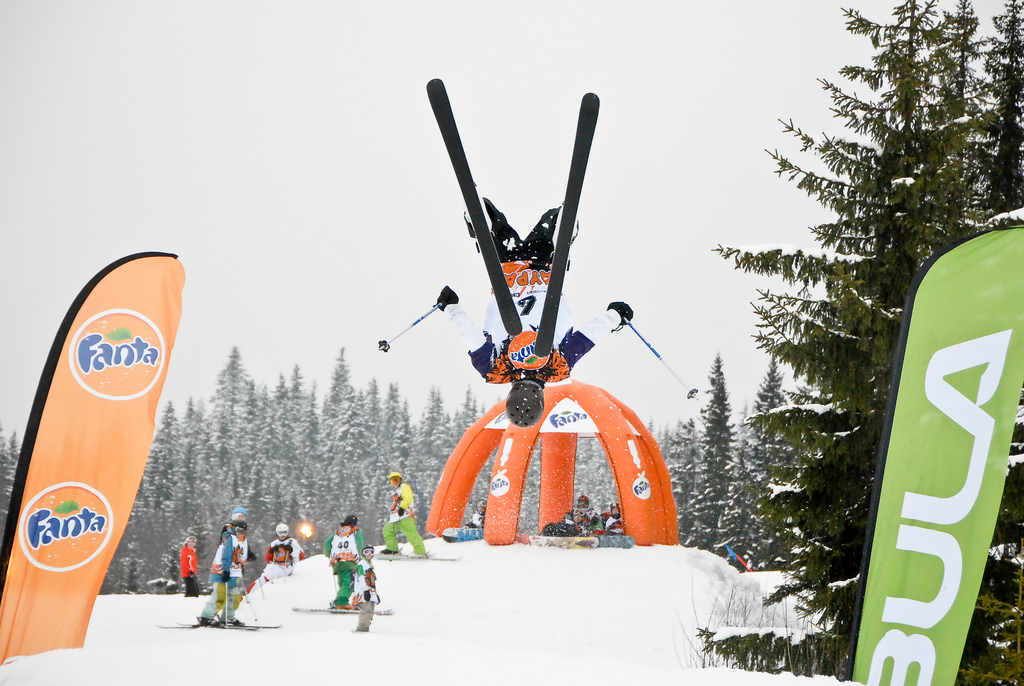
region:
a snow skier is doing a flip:
[366, 72, 708, 439]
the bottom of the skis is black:
[426, 73, 605, 358]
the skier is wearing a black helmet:
[502, 376, 548, 431]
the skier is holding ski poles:
[373, 284, 705, 417]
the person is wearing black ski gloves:
[432, 285, 641, 328]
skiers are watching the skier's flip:
[173, 465, 453, 628]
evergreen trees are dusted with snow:
[3, 323, 804, 609]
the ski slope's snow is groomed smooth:
[12, 534, 832, 683]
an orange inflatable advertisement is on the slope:
[420, 379, 680, 548]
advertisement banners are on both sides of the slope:
[10, 244, 1016, 666]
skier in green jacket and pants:
[318, 508, 367, 613]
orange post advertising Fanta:
[4, 250, 188, 659]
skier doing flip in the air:
[374, 75, 704, 429]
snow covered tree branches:
[174, 348, 432, 491]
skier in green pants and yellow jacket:
[381, 471, 430, 561]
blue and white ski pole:
[623, 310, 706, 406]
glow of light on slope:
[294, 519, 315, 536]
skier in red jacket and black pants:
[175, 531, 202, 598]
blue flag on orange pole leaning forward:
[724, 541, 751, 571]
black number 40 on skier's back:
[334, 537, 351, 554]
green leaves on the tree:
[853, 169, 933, 258]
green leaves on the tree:
[781, 560, 838, 653]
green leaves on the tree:
[850, 363, 879, 447]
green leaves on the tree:
[685, 459, 739, 504]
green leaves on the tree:
[336, 396, 395, 444]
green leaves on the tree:
[240, 434, 304, 483]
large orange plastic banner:
[0, 252, 199, 660]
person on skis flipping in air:
[377, 74, 709, 432]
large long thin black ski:
[420, 74, 528, 341]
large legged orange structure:
[429, 372, 683, 553]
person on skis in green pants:
[377, 466, 441, 559]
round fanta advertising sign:
[71, 305, 174, 398]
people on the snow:
[148, 453, 448, 659]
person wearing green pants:
[370, 461, 442, 568]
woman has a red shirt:
[171, 527, 208, 606]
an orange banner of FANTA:
[0, 232, 198, 670]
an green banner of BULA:
[840, 214, 1021, 680]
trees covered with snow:
[150, 348, 455, 503]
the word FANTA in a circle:
[61, 296, 173, 405]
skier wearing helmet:
[182, 485, 272, 635]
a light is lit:
[289, 506, 327, 555]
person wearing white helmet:
[259, 507, 311, 590]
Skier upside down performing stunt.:
[376, 71, 719, 427]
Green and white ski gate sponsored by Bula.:
[843, 191, 1021, 681]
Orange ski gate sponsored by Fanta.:
[0, 238, 193, 650]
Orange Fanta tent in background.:
[421, 367, 690, 545]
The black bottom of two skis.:
[413, 76, 610, 353]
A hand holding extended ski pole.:
[591, 300, 709, 405]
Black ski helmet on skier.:
[500, 376, 551, 427]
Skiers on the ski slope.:
[168, 466, 429, 644]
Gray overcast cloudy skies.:
[7, 0, 859, 249]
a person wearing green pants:
[374, 513, 439, 555]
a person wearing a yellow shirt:
[390, 477, 419, 515]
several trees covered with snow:
[181, 395, 378, 509]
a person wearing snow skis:
[447, 67, 607, 375]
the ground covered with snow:
[436, 556, 674, 683]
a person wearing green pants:
[332, 556, 356, 614]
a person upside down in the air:
[425, 57, 623, 446]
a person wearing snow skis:
[438, 67, 613, 377]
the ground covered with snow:
[440, 576, 672, 682]